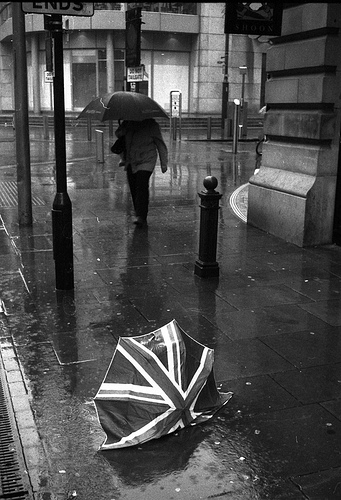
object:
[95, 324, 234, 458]
umbrella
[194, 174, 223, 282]
post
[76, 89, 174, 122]
umbrella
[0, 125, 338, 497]
sidewalk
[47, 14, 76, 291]
pole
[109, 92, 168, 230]
person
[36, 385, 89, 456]
rain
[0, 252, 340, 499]
ground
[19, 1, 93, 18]
sign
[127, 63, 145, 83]
sign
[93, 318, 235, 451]
print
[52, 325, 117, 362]
tiles